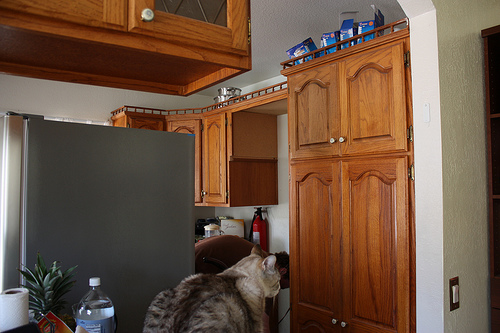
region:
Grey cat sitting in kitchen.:
[142, 240, 281, 332]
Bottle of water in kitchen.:
[73, 275, 116, 331]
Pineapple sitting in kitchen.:
[17, 253, 78, 330]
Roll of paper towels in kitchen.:
[0, 286, 27, 331]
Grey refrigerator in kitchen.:
[0, 112, 195, 331]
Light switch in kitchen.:
[448, 275, 459, 311]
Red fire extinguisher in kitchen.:
[248, 206, 269, 254]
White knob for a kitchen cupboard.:
[140, 8, 154, 21]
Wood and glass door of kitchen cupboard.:
[129, 0, 249, 57]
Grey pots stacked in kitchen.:
[213, 86, 241, 108]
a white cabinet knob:
[327, 134, 336, 145]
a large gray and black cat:
[139, 244, 285, 331]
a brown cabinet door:
[286, 60, 337, 151]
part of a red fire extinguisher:
[241, 203, 274, 251]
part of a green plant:
[15, 258, 82, 318]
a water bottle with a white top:
[70, 275, 119, 331]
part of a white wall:
[432, 0, 498, 330]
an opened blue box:
[353, 8, 385, 43]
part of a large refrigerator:
[1, 110, 208, 328]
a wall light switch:
[446, 274, 466, 315]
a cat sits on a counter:
[134, 235, 291, 331]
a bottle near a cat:
[69, 271, 116, 331]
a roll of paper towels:
[2, 278, 39, 329]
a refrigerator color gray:
[10, 98, 195, 301]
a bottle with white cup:
[74, 273, 119, 330]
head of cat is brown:
[236, 240, 286, 299]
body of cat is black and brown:
[141, 271, 251, 331]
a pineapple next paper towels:
[6, 248, 77, 330]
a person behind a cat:
[189, 216, 299, 324]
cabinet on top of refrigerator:
[20, 3, 271, 96]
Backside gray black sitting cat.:
[139, 256, 288, 330]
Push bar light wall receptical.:
[440, 254, 481, 318]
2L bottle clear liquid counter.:
[71, 266, 123, 332]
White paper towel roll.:
[0, 251, 32, 331]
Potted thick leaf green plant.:
[18, 256, 74, 322]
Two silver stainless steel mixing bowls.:
[185, 71, 255, 111]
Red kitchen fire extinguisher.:
[239, 206, 280, 256]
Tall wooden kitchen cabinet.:
[283, 59, 415, 331]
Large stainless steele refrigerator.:
[4, 103, 199, 293]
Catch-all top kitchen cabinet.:
[279, 10, 414, 80]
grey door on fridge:
[18, 115, 190, 283]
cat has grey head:
[217, 242, 283, 294]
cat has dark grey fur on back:
[143, 273, 228, 331]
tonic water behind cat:
[70, 273, 117, 331]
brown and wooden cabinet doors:
[283, 80, 425, 330]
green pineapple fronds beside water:
[21, 252, 86, 328]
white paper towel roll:
[0, 278, 41, 329]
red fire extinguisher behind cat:
[231, 204, 282, 258]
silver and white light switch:
[432, 266, 476, 308]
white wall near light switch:
[433, 72, 488, 257]